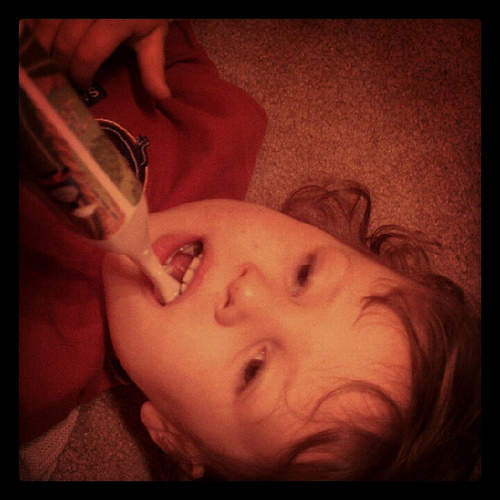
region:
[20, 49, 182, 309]
An electric toothbrush is being used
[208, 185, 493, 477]
The boy has brown hair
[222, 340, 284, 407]
The eye of the toddler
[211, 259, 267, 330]
The nose of the toddler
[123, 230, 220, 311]
The mouth of the toddler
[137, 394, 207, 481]
The ear of the toddler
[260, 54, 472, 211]
The carpet is brown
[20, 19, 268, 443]
The red shirt is on the toddler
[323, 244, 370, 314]
The eyebrow of the toddler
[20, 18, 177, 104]
The toddler's hand is bent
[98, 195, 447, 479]
face of the child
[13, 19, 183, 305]
toothbrush in child's mouth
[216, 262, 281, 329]
nose of the child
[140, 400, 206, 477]
ear of the child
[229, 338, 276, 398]
left eye of the child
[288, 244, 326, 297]
right eye of the child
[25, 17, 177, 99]
right hand of the child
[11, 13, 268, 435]
red shirt of the child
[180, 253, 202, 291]
top row of front teeth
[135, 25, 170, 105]
right thumb of child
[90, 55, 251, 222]
the shirt is red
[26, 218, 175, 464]
the shirt is red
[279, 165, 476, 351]
the hair is curly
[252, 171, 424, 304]
the hair is curly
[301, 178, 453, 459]
the hair is curly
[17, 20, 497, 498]
child laying on floor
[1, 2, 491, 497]
child laying on carpeted floor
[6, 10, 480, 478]
child wearing red shirt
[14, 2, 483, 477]
child with something in his mouth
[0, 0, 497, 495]
child with his mouth open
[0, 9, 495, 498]
child with smile on face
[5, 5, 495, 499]
child with light skin tone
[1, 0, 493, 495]
child with hand partially raised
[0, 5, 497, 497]
red shirt with embroidery on it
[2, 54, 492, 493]
child with small nose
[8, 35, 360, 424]
the kid brushing his teeth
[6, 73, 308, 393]
a green small box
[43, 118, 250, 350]
a green small box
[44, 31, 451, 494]
the kid is lying down